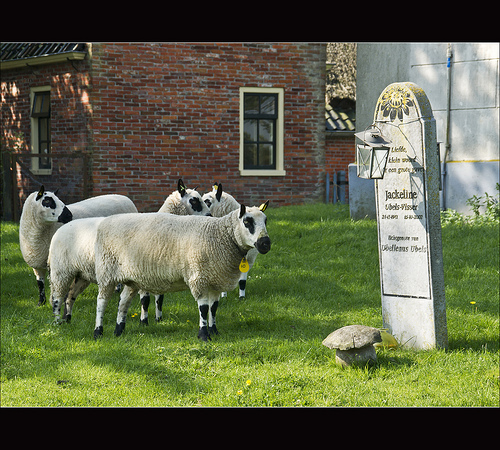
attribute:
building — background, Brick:
[8, 43, 373, 235]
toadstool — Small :
[321, 323, 389, 368]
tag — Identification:
[234, 255, 256, 287]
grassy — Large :
[4, 203, 481, 410]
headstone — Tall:
[348, 79, 452, 349]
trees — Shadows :
[438, 63, 479, 149]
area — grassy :
[14, 327, 297, 394]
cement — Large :
[351, 45, 484, 216]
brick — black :
[18, 50, 335, 200]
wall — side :
[157, 50, 207, 159]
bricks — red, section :
[121, 63, 231, 158]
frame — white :
[236, 81, 291, 179]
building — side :
[170, 43, 208, 103]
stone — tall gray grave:
[353, 83, 453, 355]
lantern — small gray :
[352, 126, 392, 181]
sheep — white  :
[9, 170, 272, 342]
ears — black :
[230, 193, 248, 223]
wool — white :
[125, 224, 174, 246]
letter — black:
[374, 184, 424, 206]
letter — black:
[381, 184, 418, 202]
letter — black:
[378, 185, 419, 206]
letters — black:
[377, 187, 418, 205]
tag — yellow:
[231, 254, 266, 277]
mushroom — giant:
[309, 302, 439, 403]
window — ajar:
[14, 65, 74, 198]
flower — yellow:
[235, 377, 275, 400]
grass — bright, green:
[173, 310, 335, 402]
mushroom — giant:
[323, 294, 383, 365]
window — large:
[231, 76, 285, 190]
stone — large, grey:
[318, 104, 467, 364]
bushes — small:
[434, 163, 499, 266]